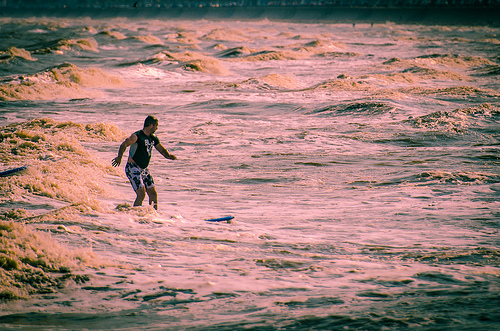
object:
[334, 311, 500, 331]
shore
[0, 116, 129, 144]
waves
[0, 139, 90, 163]
waves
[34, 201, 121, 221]
waves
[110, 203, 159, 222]
waves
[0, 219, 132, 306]
waves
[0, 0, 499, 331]
rough water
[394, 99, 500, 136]
waves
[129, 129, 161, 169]
shirt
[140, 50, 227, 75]
wave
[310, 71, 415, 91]
wave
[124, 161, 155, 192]
shorts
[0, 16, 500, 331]
ocean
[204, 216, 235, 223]
surf board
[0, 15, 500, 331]
water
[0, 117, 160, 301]
foam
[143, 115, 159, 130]
hair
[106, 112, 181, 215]
man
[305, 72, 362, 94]
wave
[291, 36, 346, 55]
waves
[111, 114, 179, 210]
man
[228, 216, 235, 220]
surfboard tip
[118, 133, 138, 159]
arm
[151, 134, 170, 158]
arm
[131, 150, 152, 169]
tank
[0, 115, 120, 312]
weeds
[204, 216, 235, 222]
tip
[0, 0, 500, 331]
hues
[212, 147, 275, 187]
reflection